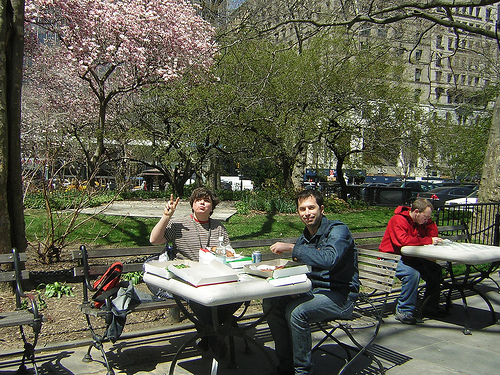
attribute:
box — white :
[168, 251, 265, 299]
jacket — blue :
[291, 218, 358, 300]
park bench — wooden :
[306, 245, 397, 373]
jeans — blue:
[281, 285, 356, 373]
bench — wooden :
[313, 248, 403, 374]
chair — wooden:
[296, 246, 402, 373]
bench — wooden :
[70, 240, 400, 374]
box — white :
[241, 256, 313, 281]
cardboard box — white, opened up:
[140, 255, 240, 287]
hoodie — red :
[359, 191, 466, 262]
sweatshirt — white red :
[377, 201, 439, 254]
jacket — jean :
[103, 277, 165, 342]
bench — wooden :
[70, 234, 237, 342]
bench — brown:
[65, 216, 479, 373]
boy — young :
[147, 182, 237, 360]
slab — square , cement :
[96, 190, 221, 220]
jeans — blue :
[262, 284, 363, 374]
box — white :
[238, 232, 301, 302]